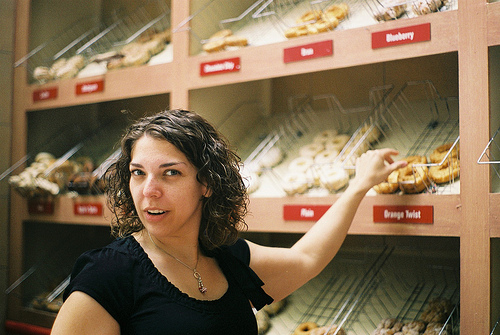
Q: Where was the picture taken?
A: In a donut shop.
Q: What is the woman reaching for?
A: A donut.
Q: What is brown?
A: Donuts.